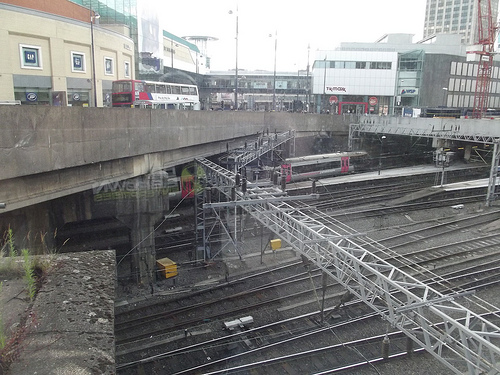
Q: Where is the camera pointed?
A: Toward railroad tracks.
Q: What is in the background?
A: Buildings.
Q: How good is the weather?
A: Not very good.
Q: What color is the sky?
A: Gray.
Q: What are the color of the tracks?
A: Silver.